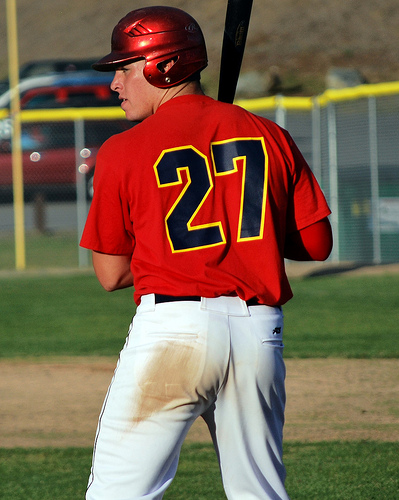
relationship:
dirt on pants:
[132, 342, 219, 424] [73, 294, 310, 496]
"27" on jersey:
[154, 136, 268, 254] [76, 93, 329, 308]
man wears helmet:
[83, 4, 237, 165] [94, 5, 215, 97]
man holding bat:
[79, 6, 332, 500] [210, 0, 269, 124]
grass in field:
[281, 273, 398, 359] [8, 206, 386, 398]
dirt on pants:
[132, 342, 219, 424] [84, 290, 292, 499]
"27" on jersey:
[159, 135, 268, 248] [107, 108, 321, 293]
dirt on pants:
[145, 335, 190, 406] [81, 293, 321, 491]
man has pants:
[79, 6, 332, 500] [130, 300, 278, 470]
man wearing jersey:
[79, 6, 332, 500] [79, 94, 333, 307]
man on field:
[79, 6, 332, 500] [0, 261, 398, 496]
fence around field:
[2, 78, 395, 289] [0, 261, 398, 496]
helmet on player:
[101, 5, 218, 87] [75, 5, 341, 454]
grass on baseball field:
[293, 277, 397, 356] [1, 78, 398, 498]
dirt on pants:
[132, 342, 219, 424] [50, 282, 324, 496]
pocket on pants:
[257, 334, 286, 380] [84, 290, 292, 499]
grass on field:
[3, 443, 393, 494] [0, 261, 398, 496]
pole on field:
[5, 0, 30, 272] [0, 261, 398, 496]